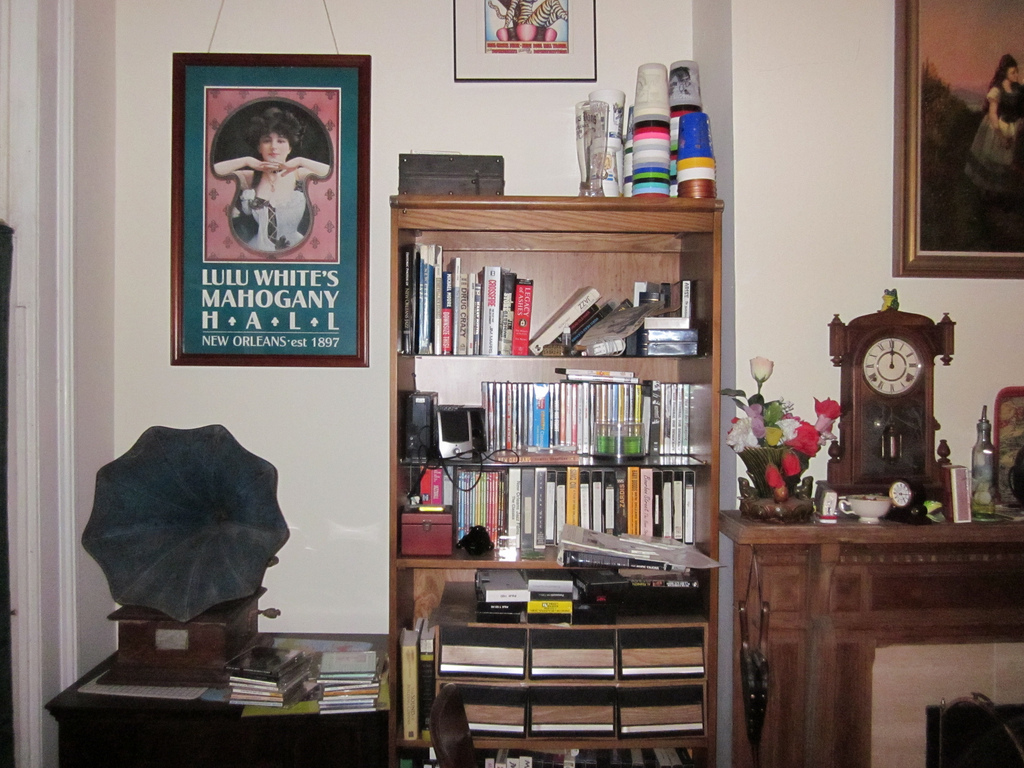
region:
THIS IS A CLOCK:
[810, 289, 972, 508]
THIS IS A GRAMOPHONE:
[67, 406, 309, 691]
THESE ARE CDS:
[223, 636, 398, 734]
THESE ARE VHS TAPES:
[400, 459, 729, 559]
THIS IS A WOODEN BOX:
[394, 501, 464, 568]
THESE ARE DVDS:
[473, 375, 712, 483]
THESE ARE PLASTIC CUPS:
[621, 61, 727, 217]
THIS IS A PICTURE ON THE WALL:
[149, 33, 385, 419]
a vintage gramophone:
[84, 423, 287, 680]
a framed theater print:
[166, 48, 373, 369]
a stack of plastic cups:
[626, 62, 671, 199]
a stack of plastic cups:
[677, 111, 713, 198]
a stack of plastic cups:
[664, 56, 703, 200]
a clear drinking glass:
[573, 95, 612, 200]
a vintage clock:
[823, 304, 953, 504]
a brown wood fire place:
[713, 509, 1021, 765]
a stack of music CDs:
[314, 651, 381, 715]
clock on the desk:
[818, 282, 970, 513]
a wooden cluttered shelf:
[375, 177, 742, 765]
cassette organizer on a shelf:
[430, 576, 719, 755]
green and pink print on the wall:
[167, 41, 382, 386]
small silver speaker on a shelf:
[436, 397, 479, 474]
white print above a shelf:
[442, 3, 604, 93]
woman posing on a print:
[209, 105, 331, 249]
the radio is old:
[80, 423, 292, 692]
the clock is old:
[825, 310, 955, 498]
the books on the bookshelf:
[386, 196, 723, 766]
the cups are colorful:
[589, 59, 719, 199]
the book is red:
[512, 281, 531, 357]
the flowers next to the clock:
[716, 309, 957, 505]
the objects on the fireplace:
[712, 287, 1022, 763]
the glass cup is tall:
[574, 97, 606, 200]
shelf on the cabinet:
[441, 633, 519, 678]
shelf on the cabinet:
[532, 644, 599, 684]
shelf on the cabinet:
[607, 639, 699, 684]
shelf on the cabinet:
[623, 701, 713, 730]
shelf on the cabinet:
[529, 698, 607, 730]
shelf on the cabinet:
[418, 692, 516, 738]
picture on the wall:
[171, 60, 369, 359]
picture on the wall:
[450, 0, 596, 84]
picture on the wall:
[873, 26, 973, 245]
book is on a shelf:
[507, 384, 515, 454]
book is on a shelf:
[659, 385, 667, 465]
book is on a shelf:
[662, 384, 672, 458]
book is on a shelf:
[675, 385, 680, 466]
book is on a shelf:
[677, 384, 684, 465]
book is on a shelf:
[672, 385, 679, 461]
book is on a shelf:
[662, 470, 676, 537]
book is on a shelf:
[671, 470, 681, 541]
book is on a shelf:
[603, 467, 620, 532]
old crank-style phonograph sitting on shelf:
[80, 421, 293, 694]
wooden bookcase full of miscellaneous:
[383, 195, 719, 766]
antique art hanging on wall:
[162, 46, 375, 373]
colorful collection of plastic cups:
[572, 55, 724, 199]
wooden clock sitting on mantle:
[825, 284, 961, 493]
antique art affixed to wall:
[877, 1, 1020, 284]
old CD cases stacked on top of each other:
[431, 574, 710, 752]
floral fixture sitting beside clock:
[718, 355, 845, 527]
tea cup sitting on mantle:
[834, 497, 899, 527]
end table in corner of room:
[40, 620, 389, 766]